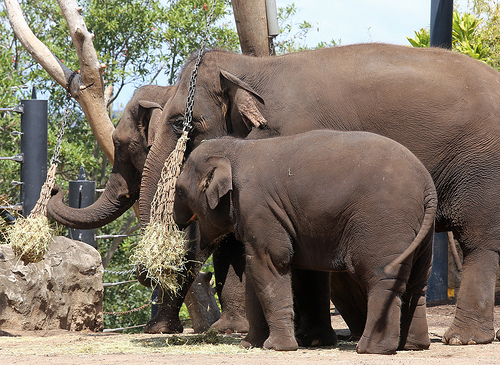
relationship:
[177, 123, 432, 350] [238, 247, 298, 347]
elephant has leg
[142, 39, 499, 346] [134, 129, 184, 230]
elephant using trunk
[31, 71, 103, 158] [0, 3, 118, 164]
chain wrapped around tree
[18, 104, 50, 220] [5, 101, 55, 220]
fence post attached to fence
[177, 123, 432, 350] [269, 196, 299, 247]
elephant has wrinkle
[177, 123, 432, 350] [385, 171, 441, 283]
elephant has tail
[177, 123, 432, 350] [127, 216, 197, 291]
elephant eating hay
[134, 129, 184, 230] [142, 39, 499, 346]
trunk on elephant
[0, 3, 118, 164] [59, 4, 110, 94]
tree has branch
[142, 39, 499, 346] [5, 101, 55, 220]
elephant near fence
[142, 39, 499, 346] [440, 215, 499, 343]
elephant has rear leg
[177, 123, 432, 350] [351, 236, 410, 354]
elephant has rear leg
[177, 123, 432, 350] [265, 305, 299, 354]
elephant has front foot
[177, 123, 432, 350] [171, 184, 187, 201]
elephant has eye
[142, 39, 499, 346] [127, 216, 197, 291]
elephant eating hay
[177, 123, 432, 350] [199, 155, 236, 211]
elephant has ear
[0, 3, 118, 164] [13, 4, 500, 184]
tree in background